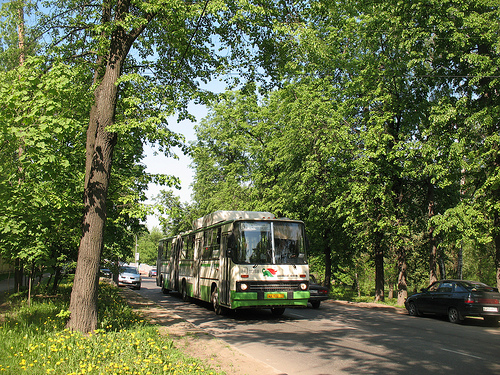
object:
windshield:
[224, 219, 306, 266]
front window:
[227, 217, 309, 266]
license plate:
[482, 306, 500, 312]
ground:
[0, 271, 500, 374]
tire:
[162, 276, 170, 294]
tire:
[212, 284, 221, 314]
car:
[113, 266, 142, 290]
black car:
[309, 274, 329, 308]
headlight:
[240, 283, 248, 291]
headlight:
[300, 283, 307, 290]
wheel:
[448, 307, 462, 323]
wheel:
[408, 304, 417, 316]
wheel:
[182, 279, 190, 302]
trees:
[0, 0, 499, 334]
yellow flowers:
[0, 309, 211, 374]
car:
[404, 279, 500, 324]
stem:
[374, 251, 385, 303]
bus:
[156, 210, 311, 315]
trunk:
[62, 51, 130, 336]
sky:
[0, 0, 500, 234]